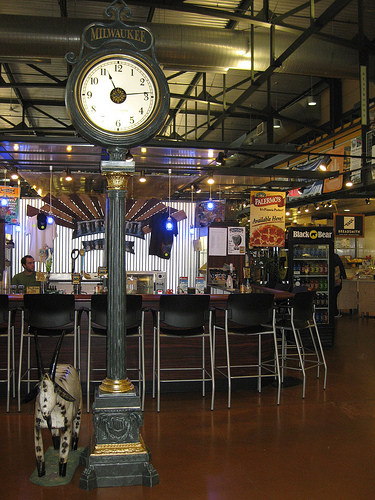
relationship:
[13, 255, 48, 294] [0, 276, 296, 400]
man standing behind bar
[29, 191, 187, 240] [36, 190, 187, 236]
brown logo for tan sign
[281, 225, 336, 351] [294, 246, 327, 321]
cooler full of drinks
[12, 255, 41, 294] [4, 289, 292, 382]
man behind bar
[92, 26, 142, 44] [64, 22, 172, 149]
lettering on clock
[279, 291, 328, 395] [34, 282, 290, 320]
chair around bar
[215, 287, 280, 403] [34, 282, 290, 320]
chair around bar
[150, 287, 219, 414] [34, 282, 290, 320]
chair around bar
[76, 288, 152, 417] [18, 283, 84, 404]
chair around chair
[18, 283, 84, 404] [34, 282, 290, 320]
chair around bar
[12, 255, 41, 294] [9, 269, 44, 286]
man in green shirt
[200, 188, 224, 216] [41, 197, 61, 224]
light hanging over bar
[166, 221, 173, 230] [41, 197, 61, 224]
light hanging over bar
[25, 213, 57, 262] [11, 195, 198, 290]
shirt hanging wall